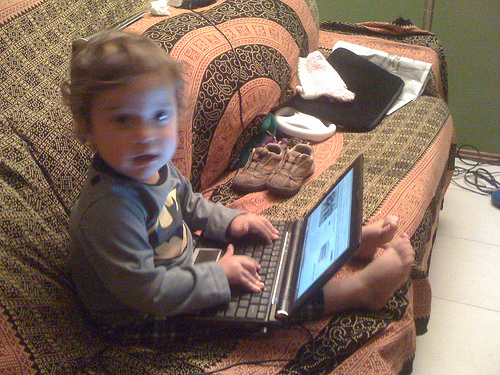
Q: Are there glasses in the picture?
A: No, there are no glasses.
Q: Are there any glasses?
A: No, there are no glasses.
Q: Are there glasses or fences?
A: No, there are no glasses or fences.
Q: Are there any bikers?
A: No, there are no bikers.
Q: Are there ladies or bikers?
A: No, there are no bikers or ladies.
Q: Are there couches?
A: Yes, there is a couch.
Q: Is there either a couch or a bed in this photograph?
A: Yes, there is a couch.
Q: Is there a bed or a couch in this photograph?
A: Yes, there is a couch.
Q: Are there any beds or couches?
A: Yes, there is a couch.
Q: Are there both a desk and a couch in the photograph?
A: No, there is a couch but no desks.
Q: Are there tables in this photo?
A: No, there are no tables.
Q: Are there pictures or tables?
A: No, there are no tables or pictures.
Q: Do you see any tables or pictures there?
A: No, there are no tables or pictures.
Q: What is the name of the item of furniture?
A: The piece of furniture is a couch.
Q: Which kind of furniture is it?
A: The piece of furniture is a couch.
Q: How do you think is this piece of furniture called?
A: That is a couch.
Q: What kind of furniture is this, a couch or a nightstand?
A: That is a couch.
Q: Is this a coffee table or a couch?
A: This is a couch.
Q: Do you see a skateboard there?
A: No, there are no skateboards.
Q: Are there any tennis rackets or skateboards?
A: No, there are no skateboards or tennis rackets.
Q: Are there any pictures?
A: No, there are no pictures.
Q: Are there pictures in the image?
A: No, there are no pictures.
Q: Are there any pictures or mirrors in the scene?
A: No, there are no pictures or mirrors.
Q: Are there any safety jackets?
A: No, there are no safety jackets.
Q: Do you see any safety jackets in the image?
A: No, there are no safety jackets.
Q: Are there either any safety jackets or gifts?
A: No, there are no safety jackets or gifts.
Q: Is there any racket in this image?
A: No, there are no rackets.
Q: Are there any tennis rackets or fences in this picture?
A: No, there are no tennis rackets or fences.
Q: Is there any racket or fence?
A: No, there are no rackets or fences.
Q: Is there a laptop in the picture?
A: Yes, there is a laptop.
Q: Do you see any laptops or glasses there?
A: Yes, there is a laptop.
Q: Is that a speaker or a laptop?
A: That is a laptop.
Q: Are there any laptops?
A: Yes, there is a laptop.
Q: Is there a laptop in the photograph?
A: Yes, there is a laptop.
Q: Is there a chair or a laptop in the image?
A: Yes, there is a laptop.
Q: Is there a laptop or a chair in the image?
A: Yes, there is a laptop.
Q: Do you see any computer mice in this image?
A: No, there are no computer mice.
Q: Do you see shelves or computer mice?
A: No, there are no computer mice or shelves.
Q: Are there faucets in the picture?
A: No, there are no faucets.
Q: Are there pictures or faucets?
A: No, there are no faucets or pictures.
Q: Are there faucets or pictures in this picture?
A: No, there are no faucets or pictures.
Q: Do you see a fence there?
A: No, there are no fences.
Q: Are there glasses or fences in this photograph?
A: No, there are no fences or glasses.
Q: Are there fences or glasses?
A: No, there are no fences or glasses.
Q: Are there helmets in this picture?
A: No, there are no helmets.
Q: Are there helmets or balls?
A: No, there are no helmets or balls.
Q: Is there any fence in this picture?
A: No, there are no fences.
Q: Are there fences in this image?
A: No, there are no fences.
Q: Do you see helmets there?
A: No, there are no helmets.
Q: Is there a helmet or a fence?
A: No, there are no helmets or fences.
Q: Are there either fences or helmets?
A: No, there are no helmets or fences.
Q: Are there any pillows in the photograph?
A: Yes, there is a pillow.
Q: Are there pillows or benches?
A: Yes, there is a pillow.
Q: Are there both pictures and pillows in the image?
A: No, there is a pillow but no pictures.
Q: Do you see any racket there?
A: No, there are no rackets.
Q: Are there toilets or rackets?
A: No, there are no rackets or toilets.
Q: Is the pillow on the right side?
A: Yes, the pillow is on the right of the image.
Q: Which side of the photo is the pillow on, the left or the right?
A: The pillow is on the right of the image.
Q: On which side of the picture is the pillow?
A: The pillow is on the right of the image.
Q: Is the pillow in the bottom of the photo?
A: No, the pillow is in the top of the image.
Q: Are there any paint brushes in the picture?
A: No, there are no paint brushes.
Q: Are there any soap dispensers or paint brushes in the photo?
A: No, there are no paint brushes or soap dispensers.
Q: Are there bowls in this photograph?
A: No, there are no bowls.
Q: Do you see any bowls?
A: No, there are no bowls.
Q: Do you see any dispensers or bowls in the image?
A: No, there are no bowls or dispensers.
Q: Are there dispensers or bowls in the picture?
A: No, there are no bowls or dispensers.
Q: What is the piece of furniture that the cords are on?
A: The piece of furniture is a couch.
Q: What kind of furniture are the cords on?
A: The cords are on the couch.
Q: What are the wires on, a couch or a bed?
A: The wires are on a couch.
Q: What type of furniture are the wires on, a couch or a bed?
A: The wires are on a couch.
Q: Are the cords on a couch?
A: Yes, the cords are on a couch.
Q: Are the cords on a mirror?
A: No, the cords are on a couch.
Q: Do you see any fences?
A: No, there are no fences.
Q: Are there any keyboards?
A: Yes, there is a keyboard.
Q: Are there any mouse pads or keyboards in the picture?
A: Yes, there is a keyboard.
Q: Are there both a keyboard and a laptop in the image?
A: Yes, there are both a keyboard and a laptop.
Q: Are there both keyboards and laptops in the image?
A: Yes, there are both a keyboard and a laptop.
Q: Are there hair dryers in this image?
A: No, there are no hair dryers.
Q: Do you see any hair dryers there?
A: No, there are no hair dryers.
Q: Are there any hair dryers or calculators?
A: No, there are no hair dryers or calculators.